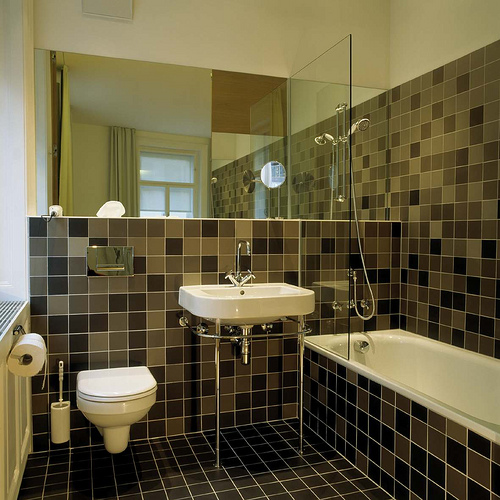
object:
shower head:
[343, 116, 374, 143]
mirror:
[48, 48, 392, 220]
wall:
[388, 0, 498, 330]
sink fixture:
[225, 239, 256, 287]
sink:
[176, 281, 316, 326]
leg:
[213, 318, 221, 466]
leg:
[297, 313, 307, 454]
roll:
[6, 326, 43, 377]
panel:
[292, 37, 345, 353]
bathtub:
[305, 318, 500, 443]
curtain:
[108, 125, 136, 217]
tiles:
[388, 42, 498, 351]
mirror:
[260, 158, 285, 188]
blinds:
[140, 150, 196, 217]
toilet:
[79, 366, 157, 453]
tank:
[82, 305, 162, 367]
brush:
[48, 359, 73, 445]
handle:
[52, 358, 64, 399]